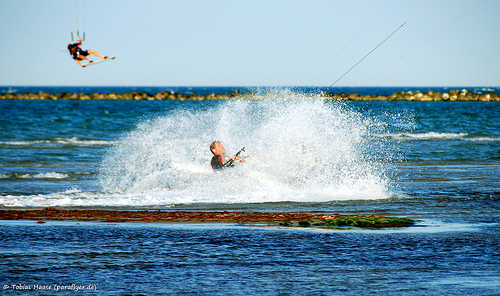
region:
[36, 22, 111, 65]
a man performing a stunt over water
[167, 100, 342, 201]
a man holding onto a rope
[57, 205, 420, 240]
a floating moat on the water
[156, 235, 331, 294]
dark blue ocean water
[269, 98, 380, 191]
white water spraying into the air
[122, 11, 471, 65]
a light blue summer sky overhead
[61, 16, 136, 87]
a man on water skii board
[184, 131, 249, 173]
a man wearing a black and red wetsuit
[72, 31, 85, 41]
a hand hoisting a body up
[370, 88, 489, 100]
a coral barrier in the ocean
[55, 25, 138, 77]
Man parasailing in the background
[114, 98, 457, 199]
Large splash of water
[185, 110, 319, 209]
Man skiing in the water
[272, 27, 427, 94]
Man being pulled with a cord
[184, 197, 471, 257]
Small spot of land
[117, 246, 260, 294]
Dark blue water no waves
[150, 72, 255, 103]
Rocky coast in front of open ocean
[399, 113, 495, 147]
Small white cap wave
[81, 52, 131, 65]
Surfboard under the man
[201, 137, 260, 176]
Man wearing a wetsuit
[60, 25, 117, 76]
person in hanging in the ski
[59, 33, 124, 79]
person stand in a surfboard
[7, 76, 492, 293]
the ocean if blue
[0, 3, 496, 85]
the sky is blue with dim white clouds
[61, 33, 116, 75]
surfer wears a black suit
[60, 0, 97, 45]
three strings supporting a surfer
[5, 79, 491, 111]
line of stones in the center of the ocean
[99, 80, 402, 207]
surfer make splashes in the water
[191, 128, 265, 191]
surfer hangs with both hands on string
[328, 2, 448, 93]
string is gray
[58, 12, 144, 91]
the man is in the air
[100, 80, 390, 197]
the water is white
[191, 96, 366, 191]
the man is wet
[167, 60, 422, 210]
the man is attatched to wires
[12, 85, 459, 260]
the water is blue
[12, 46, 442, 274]
the man is in the ocean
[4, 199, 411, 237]
the strip of land is long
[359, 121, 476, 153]
the waves are moving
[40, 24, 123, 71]
the man is wind surfing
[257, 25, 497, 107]
the rocks are in the background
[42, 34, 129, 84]
surfer in the background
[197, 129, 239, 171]
the mans head is above water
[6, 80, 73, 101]
part of a rock wall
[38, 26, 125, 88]
a person in the air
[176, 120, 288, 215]
a man surfing in the water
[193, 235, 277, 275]
dark blue water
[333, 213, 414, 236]
green part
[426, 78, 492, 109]
a bunchh of rocks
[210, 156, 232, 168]
part of the man suit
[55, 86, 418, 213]
a big splash